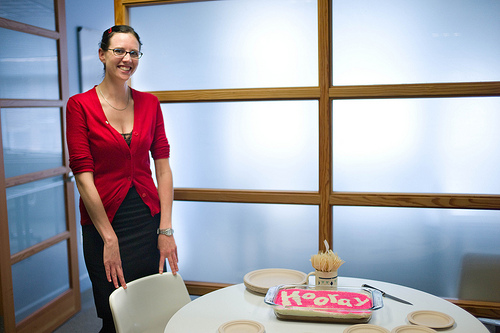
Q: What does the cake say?
A: Hooray.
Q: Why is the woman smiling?
A: Happy.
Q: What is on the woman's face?
A: Glasses.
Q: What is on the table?
A: Plates.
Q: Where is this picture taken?
A: In a conference room of an office.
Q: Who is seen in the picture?
A: A woman.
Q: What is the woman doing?
A: Standing by a table and smiling.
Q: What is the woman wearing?
A: A red sweater and a black skirt.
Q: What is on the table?
A: A pink cake with white letters and some plates.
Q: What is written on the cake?
A: "Hooray".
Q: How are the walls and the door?
A: Wood and glass panels.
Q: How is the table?
A: Round and white.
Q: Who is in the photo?
A: Woman.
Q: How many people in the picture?
A: One.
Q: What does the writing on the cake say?
A: Hooray.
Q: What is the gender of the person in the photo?
A: Female.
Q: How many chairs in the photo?
A: One.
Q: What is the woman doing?
A: Standing.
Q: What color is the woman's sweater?
A: Red.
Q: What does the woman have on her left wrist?
A: Watch.